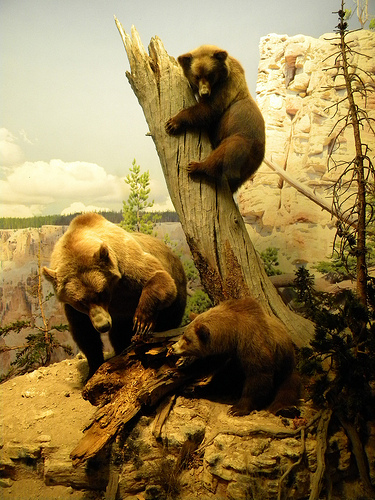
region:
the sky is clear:
[33, 79, 90, 129]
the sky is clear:
[38, 56, 87, 114]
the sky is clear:
[19, 25, 96, 106]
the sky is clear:
[28, 43, 109, 134]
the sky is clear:
[51, 120, 150, 191]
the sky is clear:
[50, 51, 119, 113]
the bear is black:
[167, 281, 309, 421]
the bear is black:
[197, 303, 289, 403]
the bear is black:
[208, 301, 268, 371]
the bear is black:
[180, 261, 273, 367]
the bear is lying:
[154, 293, 338, 401]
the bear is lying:
[185, 318, 303, 427]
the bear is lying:
[165, 282, 368, 472]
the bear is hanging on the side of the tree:
[149, 33, 278, 203]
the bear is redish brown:
[160, 36, 270, 202]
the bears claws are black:
[131, 316, 161, 344]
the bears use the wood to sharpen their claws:
[66, 349, 177, 471]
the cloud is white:
[0, 154, 122, 203]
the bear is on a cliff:
[35, 199, 202, 377]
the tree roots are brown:
[305, 407, 334, 494]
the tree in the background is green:
[115, 158, 161, 237]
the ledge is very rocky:
[0, 355, 72, 454]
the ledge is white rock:
[258, 29, 374, 255]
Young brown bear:
[92, 10, 288, 202]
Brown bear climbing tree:
[111, 12, 293, 201]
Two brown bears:
[24, 200, 332, 430]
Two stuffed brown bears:
[34, 206, 326, 434]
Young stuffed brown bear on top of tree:
[106, 8, 289, 208]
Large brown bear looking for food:
[19, 204, 186, 412]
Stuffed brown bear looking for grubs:
[29, 208, 175, 422]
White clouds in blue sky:
[10, 114, 123, 207]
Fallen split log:
[67, 309, 187, 440]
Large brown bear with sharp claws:
[28, 200, 176, 376]